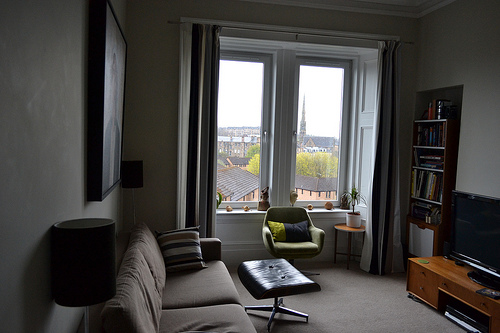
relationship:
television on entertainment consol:
[448, 190, 499, 289] [405, 256, 499, 331]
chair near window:
[259, 207, 324, 277] [218, 51, 351, 207]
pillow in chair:
[265, 219, 310, 241] [259, 207, 324, 277]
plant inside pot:
[343, 187, 365, 228] [346, 214, 361, 228]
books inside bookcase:
[410, 171, 441, 199] [409, 97, 461, 258]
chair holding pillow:
[259, 207, 324, 277] [265, 219, 310, 241]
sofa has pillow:
[95, 226, 259, 331] [154, 229, 207, 272]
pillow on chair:
[265, 219, 310, 241] [259, 207, 324, 277]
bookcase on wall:
[409, 97, 461, 258] [417, 23, 499, 282]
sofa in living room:
[95, 226, 259, 331] [1, 1, 499, 330]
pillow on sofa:
[154, 229, 207, 272] [95, 226, 259, 331]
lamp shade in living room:
[47, 221, 116, 305] [1, 1, 499, 330]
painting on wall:
[92, 0, 126, 200] [4, 4, 125, 328]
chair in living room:
[259, 207, 324, 277] [1, 1, 499, 330]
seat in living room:
[233, 256, 322, 322] [1, 1, 499, 330]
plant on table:
[343, 187, 365, 228] [332, 222, 368, 271]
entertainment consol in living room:
[405, 256, 499, 331] [1, 1, 499, 330]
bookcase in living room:
[409, 97, 461, 258] [1, 1, 499, 330]